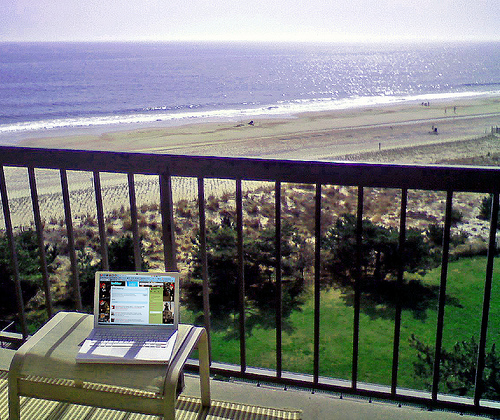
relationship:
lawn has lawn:
[171, 249, 496, 398] [171, 249, 499, 400]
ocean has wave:
[1, 39, 500, 133] [7, 110, 154, 123]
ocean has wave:
[1, 39, 500, 133] [261, 94, 398, 120]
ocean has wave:
[1, 39, 500, 133] [408, 84, 488, 102]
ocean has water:
[1, 39, 500, 133] [3, 38, 499, 134]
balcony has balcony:
[2, 147, 498, 417] [0, 145, 499, 418]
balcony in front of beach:
[0, 145, 499, 418] [5, 89, 495, 234]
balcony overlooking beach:
[2, 147, 498, 417] [5, 89, 495, 234]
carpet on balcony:
[1, 367, 302, 416] [2, 147, 498, 417]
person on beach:
[444, 105, 450, 117] [5, 89, 495, 234]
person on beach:
[452, 106, 458, 116] [5, 89, 495, 234]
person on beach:
[430, 124, 437, 133] [5, 89, 495, 234]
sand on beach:
[5, 92, 496, 228] [5, 89, 495, 234]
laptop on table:
[75, 272, 180, 363] [9, 312, 210, 418]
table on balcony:
[9, 312, 210, 418] [2, 147, 498, 417]